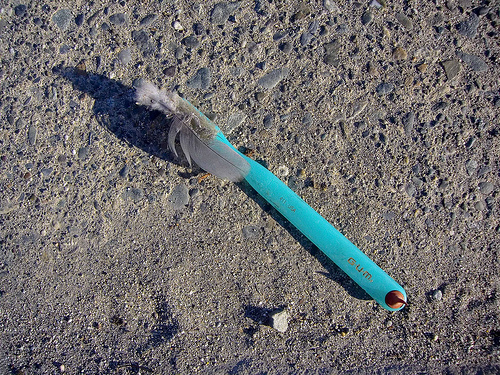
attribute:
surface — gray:
[277, 67, 368, 128]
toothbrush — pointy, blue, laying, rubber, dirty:
[141, 21, 408, 310]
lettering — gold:
[337, 245, 379, 284]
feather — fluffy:
[191, 155, 262, 176]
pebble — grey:
[18, 12, 94, 43]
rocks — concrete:
[271, 0, 347, 35]